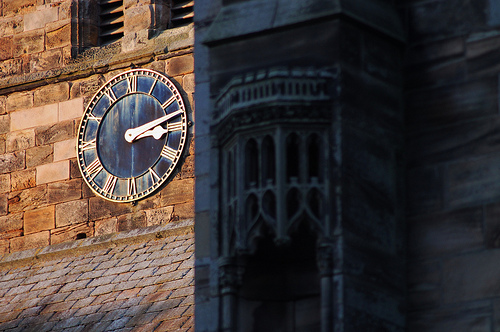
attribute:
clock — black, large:
[83, 61, 181, 204]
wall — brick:
[0, 105, 80, 316]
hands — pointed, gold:
[123, 114, 177, 144]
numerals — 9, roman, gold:
[108, 69, 150, 91]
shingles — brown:
[161, 284, 185, 308]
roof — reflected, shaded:
[1, 236, 193, 326]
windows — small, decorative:
[68, 0, 170, 47]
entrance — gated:
[244, 244, 321, 324]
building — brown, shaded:
[39, 90, 474, 321]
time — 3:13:
[157, 90, 184, 139]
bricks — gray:
[17, 255, 90, 286]